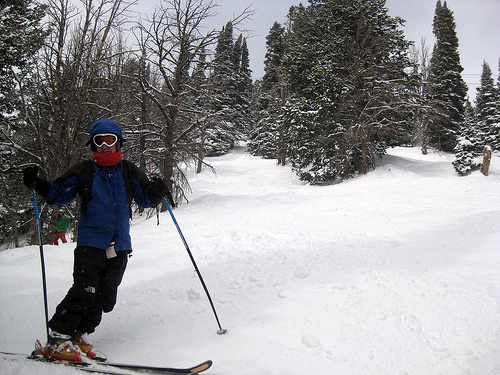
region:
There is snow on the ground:
[38, 180, 488, 361]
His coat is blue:
[57, 167, 142, 247]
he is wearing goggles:
[72, 115, 124, 154]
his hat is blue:
[87, 113, 121, 135]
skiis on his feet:
[3, 328, 208, 373]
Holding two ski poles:
[147, 183, 232, 327]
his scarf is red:
[85, 140, 130, 168]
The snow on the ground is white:
[187, 239, 465, 367]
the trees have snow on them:
[282, 19, 394, 162]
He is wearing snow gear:
[39, 114, 187, 363]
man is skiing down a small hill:
[40, 107, 215, 369]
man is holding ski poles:
[132, 163, 269, 354]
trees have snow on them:
[270, 30, 485, 162]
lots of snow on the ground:
[276, 213, 427, 338]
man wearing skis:
[10, 322, 245, 369]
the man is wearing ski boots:
[30, 325, 110, 366]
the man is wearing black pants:
[35, 255, 150, 345]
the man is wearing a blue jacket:
[48, 155, 183, 268]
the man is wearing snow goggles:
[85, 127, 153, 179]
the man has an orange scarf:
[82, 144, 134, 178]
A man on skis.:
[10, 110, 215, 362]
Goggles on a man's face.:
[90, 131, 119, 148]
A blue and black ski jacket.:
[24, 155, 167, 241]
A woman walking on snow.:
[48, 206, 73, 248]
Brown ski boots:
[40, 327, 107, 363]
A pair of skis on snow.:
[3, 353, 253, 373]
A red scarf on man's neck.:
[90, 149, 128, 171]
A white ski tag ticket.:
[97, 238, 117, 260]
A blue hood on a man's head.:
[85, 122, 125, 146]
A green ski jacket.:
[52, 215, 69, 232]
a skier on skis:
[5, 108, 178, 368]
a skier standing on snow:
[0, 102, 201, 374]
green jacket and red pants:
[44, 208, 73, 249]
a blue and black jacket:
[28, 123, 164, 262]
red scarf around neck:
[85, 148, 139, 178]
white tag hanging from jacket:
[103, 238, 129, 273]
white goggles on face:
[88, 134, 133, 154]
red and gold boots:
[28, 327, 107, 368]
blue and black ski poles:
[151, 195, 235, 338]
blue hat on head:
[86, 108, 134, 148]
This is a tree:
[156, 2, 198, 229]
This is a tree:
[129, 25, 162, 206]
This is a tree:
[52, 9, 84, 220]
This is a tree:
[193, 43, 223, 193]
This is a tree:
[429, 5, 461, 175]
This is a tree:
[472, 53, 495, 170]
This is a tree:
[314, 5, 372, 195]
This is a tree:
[261, 20, 291, 169]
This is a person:
[15, 113, 192, 361]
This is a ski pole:
[153, 165, 272, 368]